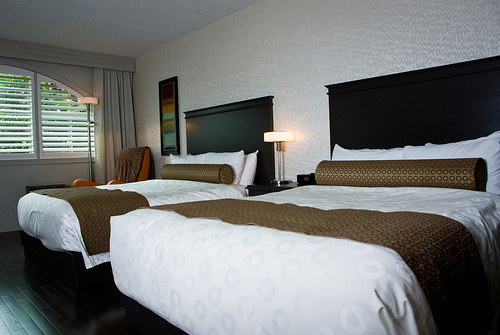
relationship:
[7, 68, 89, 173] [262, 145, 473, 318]
window near bed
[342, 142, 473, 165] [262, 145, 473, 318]
pillow on bed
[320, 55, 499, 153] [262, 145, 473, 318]
headboard on bed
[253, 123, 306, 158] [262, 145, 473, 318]
lamp near bed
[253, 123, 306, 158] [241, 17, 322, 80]
lamp near wall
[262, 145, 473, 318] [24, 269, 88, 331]
bed near floor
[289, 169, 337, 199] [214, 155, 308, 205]
clock on nightstand